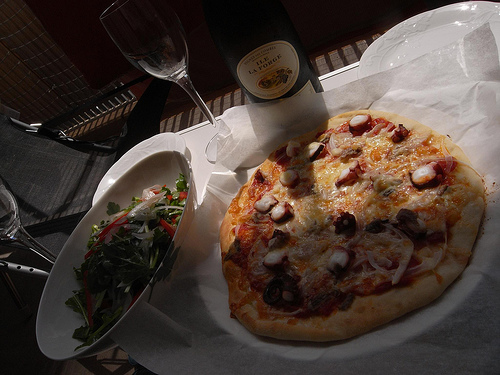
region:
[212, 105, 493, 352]
a cooked pizza with onions and sausage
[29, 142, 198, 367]
a salad in a bowl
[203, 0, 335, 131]
a dark bottle of wine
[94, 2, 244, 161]
an empty wine glass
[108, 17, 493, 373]
pizza on white paper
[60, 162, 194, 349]
a green, red and white salad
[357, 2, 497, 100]
a white plate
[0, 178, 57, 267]
an empty wine glass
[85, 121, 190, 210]
a white plate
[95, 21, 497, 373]
a white plate under white paper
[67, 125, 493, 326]
Pizza and a salad on a table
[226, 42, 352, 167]
Bottle of wine behind the pizza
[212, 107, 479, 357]
Pizza rests on top of parchment paper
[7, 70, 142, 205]
Black lounge chair beside table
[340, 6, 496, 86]
Empty white plate under paper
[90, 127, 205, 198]
Empty white bowl behind salad bowl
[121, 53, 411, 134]
Shadow of a fence on the floor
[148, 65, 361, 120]
Wooden planked floor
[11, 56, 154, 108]
Room divider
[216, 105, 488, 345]
A pizza with onions and cheese.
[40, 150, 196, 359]
Salad in a white bowl.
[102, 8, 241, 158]
An empty glass sitting by wine.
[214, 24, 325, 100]
A bottle of wine on a table.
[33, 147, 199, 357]
A white bowl filled with salad.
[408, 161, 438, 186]
A radish on a pizza.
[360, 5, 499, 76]
An empty white plate on a table.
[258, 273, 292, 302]
An olive on some pizza.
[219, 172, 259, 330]
Melted cheese on a pizza crust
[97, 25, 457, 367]
A white napkin under a pizza.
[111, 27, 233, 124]
a clear glass for wine.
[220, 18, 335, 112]
a front of a bottle of wine and label.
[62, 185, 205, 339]
a salad in a white rounded bowl.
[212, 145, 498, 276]
part of a pizza on a white plate.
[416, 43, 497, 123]
a white paper napkin type area.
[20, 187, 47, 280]
part of a wine glass stem.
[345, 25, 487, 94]
Part of an empty white plate.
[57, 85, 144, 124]
a black metal grating.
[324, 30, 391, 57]
Part of a shadow from the metal grating.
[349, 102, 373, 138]
a purple an white topping for the pizza.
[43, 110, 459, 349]
Pizza and salad on the table.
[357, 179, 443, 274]
The pizza has white cheese.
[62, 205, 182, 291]
The salad in a white bowl.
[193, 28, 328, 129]
A wine bottle next to the pizza.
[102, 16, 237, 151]
A wine glasson the table.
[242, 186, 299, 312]
The pizza has black olives and meat on it.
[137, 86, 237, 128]
Reflection on the table.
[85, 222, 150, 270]
The salad has lettuce.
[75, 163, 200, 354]
The bowl is white.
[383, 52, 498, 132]
A white wrapper under the pizza.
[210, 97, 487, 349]
a small round pizza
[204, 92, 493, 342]
a pizza with toppings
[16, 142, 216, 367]
a bowl of vegetables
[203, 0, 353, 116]
a bottle of wine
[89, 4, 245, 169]
a clear wine glass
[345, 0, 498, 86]
a white ceramic plate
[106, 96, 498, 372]
a pizza on wax paper